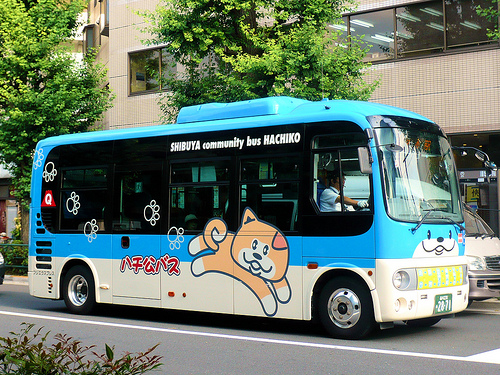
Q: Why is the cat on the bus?
A: Decoration.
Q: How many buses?
A: 1.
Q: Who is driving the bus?
A: The driver.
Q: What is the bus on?
A: Road.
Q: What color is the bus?
A: Blue.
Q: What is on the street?
A: Bus.